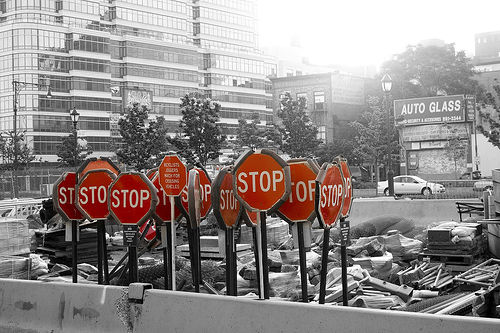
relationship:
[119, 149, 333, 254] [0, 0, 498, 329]
signs in yard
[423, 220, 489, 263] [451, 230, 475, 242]
stack of sand bag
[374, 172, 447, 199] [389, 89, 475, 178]
car in front of business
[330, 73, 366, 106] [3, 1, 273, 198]
sign of building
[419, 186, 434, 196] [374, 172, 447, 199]
tire on car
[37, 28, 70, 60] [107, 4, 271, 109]
window on building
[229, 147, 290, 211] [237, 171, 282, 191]
sign with letters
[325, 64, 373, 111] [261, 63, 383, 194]
sign on building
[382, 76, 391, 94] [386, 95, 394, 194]
street lamp on black pole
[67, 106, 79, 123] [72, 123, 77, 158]
street lamp on black pole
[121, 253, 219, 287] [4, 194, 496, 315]
fence on ground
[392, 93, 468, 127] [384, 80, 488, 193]
advertisement sign on top of building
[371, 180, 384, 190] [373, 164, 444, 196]
taillight on car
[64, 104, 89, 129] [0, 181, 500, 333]
light above ground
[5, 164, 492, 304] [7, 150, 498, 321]
supplies in enclosed area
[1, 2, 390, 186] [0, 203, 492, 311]
buildings are behind small bridge